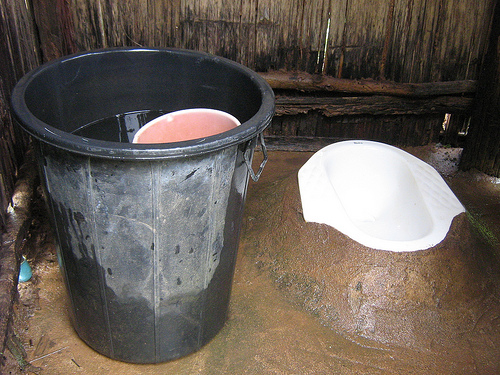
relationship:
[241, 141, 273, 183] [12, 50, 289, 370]
handle on a bucket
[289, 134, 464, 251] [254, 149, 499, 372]
hole in ground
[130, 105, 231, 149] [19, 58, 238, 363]
object in bucket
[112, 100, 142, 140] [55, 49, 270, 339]
reflection in bucket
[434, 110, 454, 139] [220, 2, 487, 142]
hole in wall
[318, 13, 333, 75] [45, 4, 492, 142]
crack in wood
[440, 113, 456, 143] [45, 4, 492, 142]
crack in wood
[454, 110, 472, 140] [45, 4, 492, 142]
crack in wood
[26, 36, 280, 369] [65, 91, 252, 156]
bucket with water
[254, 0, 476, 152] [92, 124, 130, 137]
wood from water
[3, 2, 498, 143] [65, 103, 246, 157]
rotten wood from water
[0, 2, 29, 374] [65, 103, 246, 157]
rotten wood from water